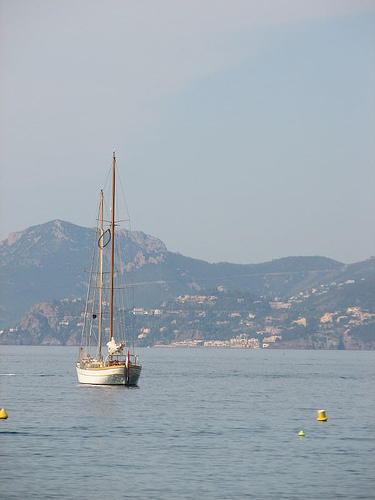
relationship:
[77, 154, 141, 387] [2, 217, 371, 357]
boat sailing in front of mountains